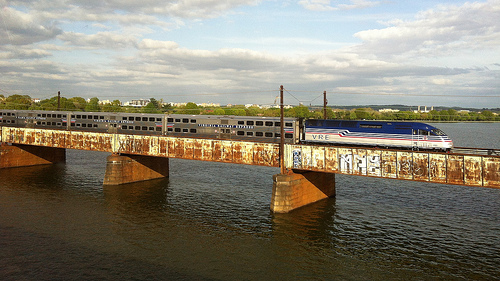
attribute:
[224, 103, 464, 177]
train — blue, car, crossing, travelling, track, moving, bridge, metal, fast, engine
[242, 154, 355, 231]
pillar — bridge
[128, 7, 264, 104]
day — cloudy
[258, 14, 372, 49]
sky — blue, cloudy, cloud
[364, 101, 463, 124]
tree — row, background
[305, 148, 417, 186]
bridge — white, support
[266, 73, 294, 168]
pole — electrical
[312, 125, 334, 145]
sign — vre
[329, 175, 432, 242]
water — body, calm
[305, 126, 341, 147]
letter — blue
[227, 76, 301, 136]
line — power